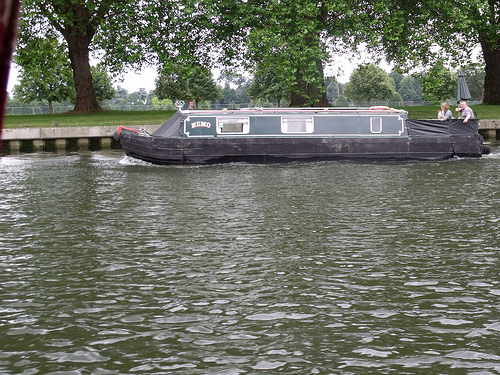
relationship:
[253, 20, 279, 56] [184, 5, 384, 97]
leaves of tree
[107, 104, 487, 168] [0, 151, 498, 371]
boat on water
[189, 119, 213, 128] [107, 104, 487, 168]
word on boat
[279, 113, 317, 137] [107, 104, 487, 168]
window on boat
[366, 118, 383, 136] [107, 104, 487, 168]
window on boat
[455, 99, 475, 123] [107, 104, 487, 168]
man on boat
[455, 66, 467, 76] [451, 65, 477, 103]
top of umbrella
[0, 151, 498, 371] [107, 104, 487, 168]
water in front of boat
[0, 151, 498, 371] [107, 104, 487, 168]
water with boat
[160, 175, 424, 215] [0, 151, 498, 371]
ripple of water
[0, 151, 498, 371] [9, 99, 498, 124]
water in park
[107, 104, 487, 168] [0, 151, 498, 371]
boat in water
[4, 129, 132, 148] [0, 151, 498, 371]
structure near water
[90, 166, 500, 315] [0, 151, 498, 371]
ripple in water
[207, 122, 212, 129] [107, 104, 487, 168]
word on boat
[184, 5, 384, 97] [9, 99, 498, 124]
tree in park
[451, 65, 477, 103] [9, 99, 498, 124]
tent in park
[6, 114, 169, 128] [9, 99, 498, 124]
grass in park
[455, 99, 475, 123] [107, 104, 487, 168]
man riding on boat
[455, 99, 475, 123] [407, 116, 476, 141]
man sitting in back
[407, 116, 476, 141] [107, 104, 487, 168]
back of boat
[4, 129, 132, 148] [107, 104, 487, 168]
wall next to boat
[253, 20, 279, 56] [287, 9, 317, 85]
leaves hanging from branches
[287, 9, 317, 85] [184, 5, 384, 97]
branches of tree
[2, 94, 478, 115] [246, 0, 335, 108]
fence behind tree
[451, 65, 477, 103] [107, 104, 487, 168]
umbrella sitting on boat